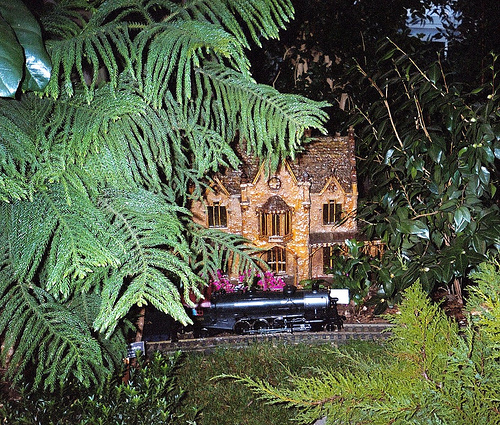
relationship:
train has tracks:
[166, 279, 343, 341] [121, 322, 391, 354]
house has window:
[170, 133, 392, 289] [321, 201, 342, 226]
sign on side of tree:
[123, 341, 147, 360] [3, 3, 332, 391]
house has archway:
[170, 133, 392, 289] [256, 246, 300, 293]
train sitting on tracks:
[166, 279, 343, 341] [121, 322, 391, 354]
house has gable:
[170, 133, 392, 289] [318, 175, 350, 196]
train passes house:
[166, 279, 343, 341] [170, 133, 392, 289]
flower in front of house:
[275, 279, 285, 292] [170, 133, 392, 289]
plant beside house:
[334, 118, 498, 314] [170, 133, 392, 289]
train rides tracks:
[166, 279, 343, 341] [121, 322, 391, 354]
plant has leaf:
[334, 118, 498, 314] [451, 207, 465, 228]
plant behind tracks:
[334, 118, 498, 314] [121, 322, 391, 354]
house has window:
[170, 133, 392, 289] [257, 197, 296, 244]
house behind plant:
[170, 133, 392, 289] [334, 118, 498, 314]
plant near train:
[334, 118, 498, 314] [166, 279, 343, 341]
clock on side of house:
[266, 175, 280, 194] [170, 133, 392, 289]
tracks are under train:
[121, 322, 391, 354] [166, 279, 343, 341]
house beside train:
[170, 133, 392, 289] [166, 279, 343, 341]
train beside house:
[166, 279, 343, 341] [170, 133, 392, 289]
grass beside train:
[161, 340, 391, 422] [166, 279, 343, 341]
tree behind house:
[273, 0, 430, 126] [170, 133, 392, 289]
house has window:
[170, 133, 392, 289] [206, 205, 230, 229]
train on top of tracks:
[166, 279, 343, 341] [121, 322, 391, 354]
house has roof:
[170, 133, 392, 289] [186, 135, 360, 195]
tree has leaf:
[3, 3, 332, 391] [451, 207, 465, 228]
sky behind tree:
[401, 2, 474, 62] [3, 3, 332, 391]